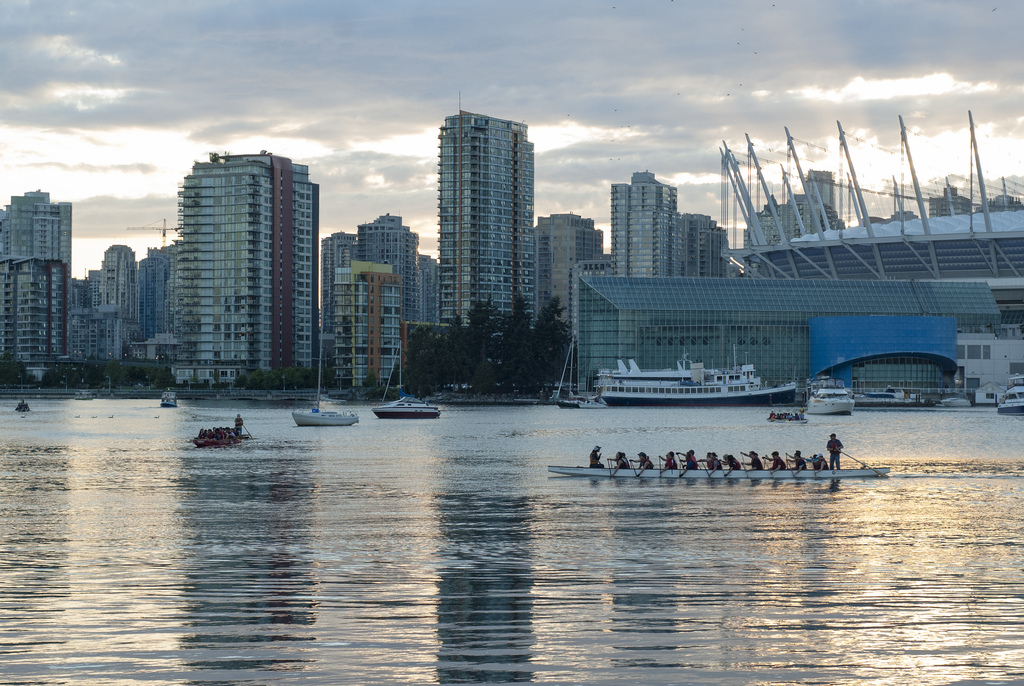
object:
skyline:
[6, 64, 1022, 257]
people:
[578, 432, 607, 473]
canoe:
[525, 431, 911, 494]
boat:
[288, 390, 364, 440]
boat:
[559, 335, 802, 419]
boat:
[365, 389, 451, 428]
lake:
[0, 395, 1024, 685]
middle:
[340, 76, 691, 428]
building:
[0, 105, 1024, 394]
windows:
[377, 344, 404, 357]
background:
[0, 107, 1022, 409]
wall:
[606, 293, 1013, 397]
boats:
[750, 384, 825, 435]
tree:
[501, 284, 569, 400]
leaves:
[517, 341, 533, 351]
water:
[0, 398, 1024, 670]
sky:
[0, 0, 1021, 257]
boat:
[802, 370, 873, 425]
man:
[821, 416, 861, 490]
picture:
[0, 0, 1021, 686]